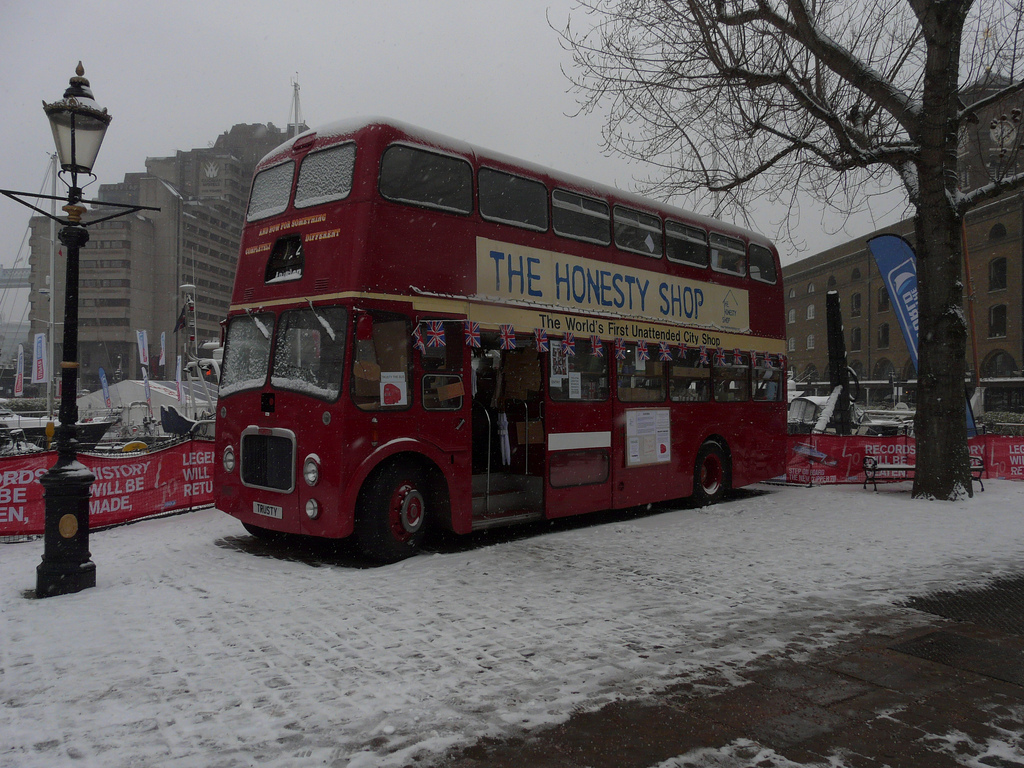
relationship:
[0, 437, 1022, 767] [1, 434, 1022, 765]
snow on ground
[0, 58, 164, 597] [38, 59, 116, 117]
iron with snow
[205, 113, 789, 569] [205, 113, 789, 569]
big level big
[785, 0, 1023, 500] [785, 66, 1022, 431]
background in background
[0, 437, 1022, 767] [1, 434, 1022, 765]
snow covering ground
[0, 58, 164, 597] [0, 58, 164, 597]
iron street iron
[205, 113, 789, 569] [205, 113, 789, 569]
big red big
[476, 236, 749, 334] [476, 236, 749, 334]
advertisment with advertisment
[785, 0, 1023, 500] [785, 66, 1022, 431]
background in distance.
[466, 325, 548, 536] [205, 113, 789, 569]
door on big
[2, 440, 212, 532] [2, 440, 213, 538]
red and white.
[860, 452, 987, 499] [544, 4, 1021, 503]
bench behind leaves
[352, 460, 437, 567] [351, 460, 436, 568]
big red big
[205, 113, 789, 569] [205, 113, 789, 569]
big british big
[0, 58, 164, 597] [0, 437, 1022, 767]
iron and snow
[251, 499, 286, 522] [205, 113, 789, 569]
plate on big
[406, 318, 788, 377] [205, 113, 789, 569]
flag decorating big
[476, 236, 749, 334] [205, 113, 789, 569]
advertisment on big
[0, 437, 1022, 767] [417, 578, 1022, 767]
snow on cobblestone.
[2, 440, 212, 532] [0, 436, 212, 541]
red on banners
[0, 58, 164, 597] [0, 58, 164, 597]
iron behind iron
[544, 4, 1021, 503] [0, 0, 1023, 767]
leaves in winter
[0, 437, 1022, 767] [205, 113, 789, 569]
snow on big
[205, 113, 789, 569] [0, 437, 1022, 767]
big on snow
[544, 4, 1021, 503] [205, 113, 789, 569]
leaves near big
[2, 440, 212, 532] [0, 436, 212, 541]
red construction fencing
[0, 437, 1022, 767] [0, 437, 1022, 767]
snow atop snow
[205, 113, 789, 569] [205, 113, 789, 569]
big of big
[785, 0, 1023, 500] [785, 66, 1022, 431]
background in background.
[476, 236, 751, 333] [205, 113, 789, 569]
advertisment along big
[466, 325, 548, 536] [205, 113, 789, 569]
doorway into big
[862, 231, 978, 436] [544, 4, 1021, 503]
sign behind leaves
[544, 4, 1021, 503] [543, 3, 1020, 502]
leaves without leaves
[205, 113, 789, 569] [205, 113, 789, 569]
big decker big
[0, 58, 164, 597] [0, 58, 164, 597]
iron lamp iron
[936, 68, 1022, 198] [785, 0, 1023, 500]
clocktower on background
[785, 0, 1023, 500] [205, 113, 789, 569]
background behind big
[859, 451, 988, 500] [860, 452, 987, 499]
metal park bench.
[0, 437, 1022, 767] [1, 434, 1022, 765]
snow covering ground.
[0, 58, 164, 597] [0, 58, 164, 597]
iron fashioned iron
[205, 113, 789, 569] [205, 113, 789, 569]
big converted into a big